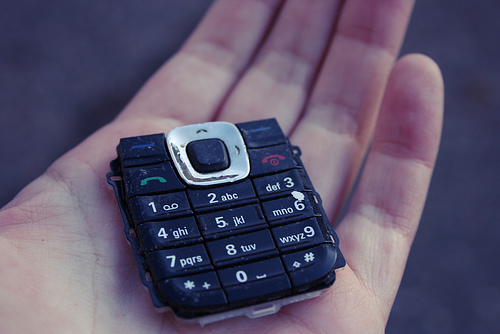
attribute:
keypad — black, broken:
[120, 125, 338, 293]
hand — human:
[8, 2, 446, 333]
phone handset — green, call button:
[139, 175, 169, 185]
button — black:
[125, 163, 179, 191]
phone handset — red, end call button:
[261, 152, 287, 165]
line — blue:
[247, 125, 277, 136]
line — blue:
[131, 139, 159, 153]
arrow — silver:
[190, 124, 213, 138]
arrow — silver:
[232, 141, 244, 159]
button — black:
[127, 194, 190, 217]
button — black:
[250, 173, 313, 198]